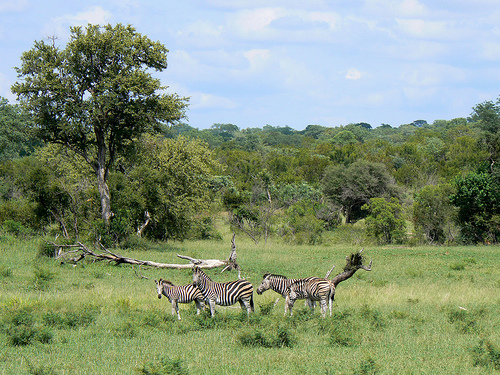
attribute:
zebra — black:
[154, 276, 214, 319]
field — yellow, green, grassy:
[1, 235, 499, 372]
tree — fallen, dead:
[53, 234, 245, 284]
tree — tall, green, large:
[11, 23, 192, 245]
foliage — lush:
[356, 170, 500, 244]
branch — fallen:
[96, 240, 121, 257]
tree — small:
[318, 158, 407, 226]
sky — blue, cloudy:
[0, 1, 499, 129]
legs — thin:
[319, 296, 335, 320]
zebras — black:
[153, 264, 338, 323]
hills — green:
[149, 112, 496, 207]